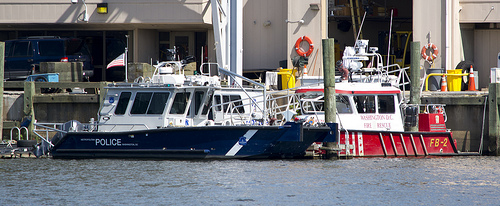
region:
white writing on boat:
[66, 119, 148, 168]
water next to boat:
[133, 161, 216, 203]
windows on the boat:
[103, 78, 193, 126]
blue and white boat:
[53, 62, 301, 186]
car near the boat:
[0, 19, 102, 89]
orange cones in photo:
[421, 55, 484, 109]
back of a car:
[49, 24, 105, 98]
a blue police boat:
[47, 74, 341, 165]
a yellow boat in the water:
[300, 80, 464, 171]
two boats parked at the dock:
[50, 61, 467, 163]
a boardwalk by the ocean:
[4, 74, 485, 171]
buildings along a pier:
[11, 0, 498, 80]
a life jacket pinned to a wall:
[422, 38, 437, 63]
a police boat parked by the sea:
[57, 67, 335, 154]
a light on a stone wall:
[64, 3, 126, 24]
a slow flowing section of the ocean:
[5, 154, 492, 202]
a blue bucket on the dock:
[18, 64, 68, 91]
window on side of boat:
[110, 90, 133, 116]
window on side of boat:
[131, 91, 153, 114]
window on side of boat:
[147, 91, 167, 115]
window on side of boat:
[335, 95, 354, 113]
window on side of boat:
[353, 94, 377, 112]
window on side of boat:
[375, 92, 394, 113]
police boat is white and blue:
[52, 45, 333, 163]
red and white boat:
[290, 36, 464, 158]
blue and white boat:
[46, 45, 336, 161]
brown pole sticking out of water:
[321, 40, 339, 158]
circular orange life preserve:
[292, 35, 314, 60]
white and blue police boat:
[40, 50, 332, 166]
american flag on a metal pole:
[101, 45, 131, 82]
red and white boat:
[300, 77, 462, 157]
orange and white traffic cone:
[465, 62, 479, 91]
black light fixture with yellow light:
[94, 0, 110, 18]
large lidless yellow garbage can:
[445, 65, 462, 93]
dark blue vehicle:
[0, 33, 96, 87]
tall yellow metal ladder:
[346, 0, 363, 43]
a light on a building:
[88, 0, 115, 17]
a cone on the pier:
[463, 58, 480, 97]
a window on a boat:
[354, 91, 388, 117]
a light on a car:
[58, 49, 69, 68]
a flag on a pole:
[104, 40, 143, 86]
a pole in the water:
[322, 129, 352, 169]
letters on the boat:
[425, 135, 455, 152]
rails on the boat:
[223, 87, 265, 132]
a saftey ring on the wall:
[285, 43, 330, 58]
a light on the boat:
[102, 85, 126, 117]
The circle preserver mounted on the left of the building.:
[292, 35, 312, 55]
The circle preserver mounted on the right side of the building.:
[420, 45, 435, 60]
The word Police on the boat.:
[94, 137, 119, 147]